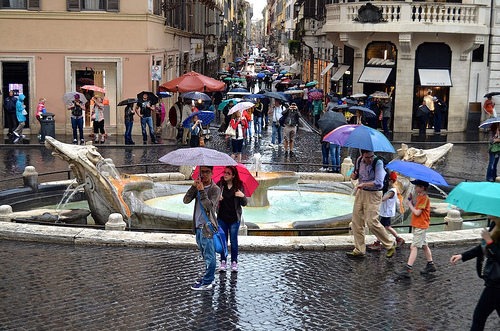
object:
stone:
[38, 0, 69, 12]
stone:
[117, 1, 156, 17]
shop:
[391, 33, 474, 143]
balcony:
[320, 1, 488, 36]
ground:
[0, 236, 499, 331]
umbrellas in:
[347, 91, 369, 99]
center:
[1, 79, 500, 322]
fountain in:
[0, 134, 499, 251]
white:
[426, 75, 448, 85]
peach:
[1, 0, 258, 138]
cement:
[66, 146, 84, 152]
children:
[392, 177, 437, 276]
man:
[345, 146, 398, 259]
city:
[0, 0, 499, 331]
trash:
[37, 112, 55, 144]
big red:
[155, 67, 228, 94]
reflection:
[157, 242, 311, 330]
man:
[181, 163, 224, 292]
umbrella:
[444, 181, 499, 220]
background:
[0, 0, 498, 328]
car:
[247, 58, 256, 65]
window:
[26, 0, 42, 12]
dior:
[85, 67, 105, 77]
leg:
[406, 232, 423, 268]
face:
[197, 165, 214, 183]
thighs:
[215, 218, 228, 256]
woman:
[215, 165, 248, 274]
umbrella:
[382, 159, 450, 188]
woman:
[11, 91, 27, 138]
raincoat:
[13, 93, 28, 123]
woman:
[225, 109, 246, 165]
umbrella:
[225, 101, 258, 117]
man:
[134, 91, 161, 145]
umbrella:
[136, 90, 161, 108]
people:
[447, 213, 499, 330]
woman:
[122, 101, 138, 147]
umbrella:
[116, 96, 141, 109]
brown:
[224, 198, 236, 213]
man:
[281, 100, 302, 158]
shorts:
[280, 127, 299, 145]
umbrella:
[320, 122, 397, 153]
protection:
[157, 146, 240, 167]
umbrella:
[262, 89, 289, 102]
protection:
[347, 105, 376, 118]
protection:
[180, 91, 215, 103]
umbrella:
[182, 108, 219, 130]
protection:
[179, 110, 213, 129]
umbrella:
[61, 90, 88, 109]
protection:
[80, 84, 106, 92]